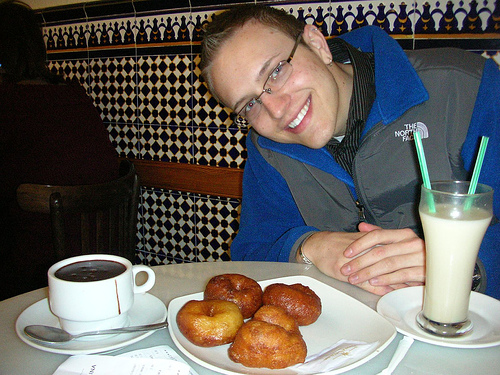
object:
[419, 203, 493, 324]
milk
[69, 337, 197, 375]
slips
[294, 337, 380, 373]
packet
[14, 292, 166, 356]
plate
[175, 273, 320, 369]
donuts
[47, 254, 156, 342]
cup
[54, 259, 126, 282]
chocolate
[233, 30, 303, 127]
eyeglasses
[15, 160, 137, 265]
chair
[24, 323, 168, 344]
spoon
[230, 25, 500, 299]
jacket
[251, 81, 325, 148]
smiling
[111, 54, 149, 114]
tiles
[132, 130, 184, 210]
wall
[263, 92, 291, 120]
nose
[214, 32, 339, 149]
face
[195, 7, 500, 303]
man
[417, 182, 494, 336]
glass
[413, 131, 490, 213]
straws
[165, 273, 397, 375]
plate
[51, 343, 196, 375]
receipt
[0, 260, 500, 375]
table